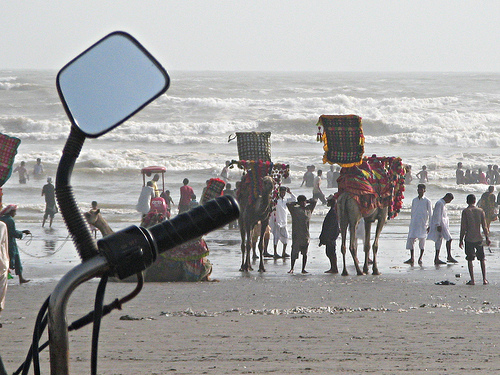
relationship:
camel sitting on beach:
[226, 167, 283, 274] [0, 225, 498, 374]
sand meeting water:
[212, 251, 239, 349] [211, 79, 415, 151]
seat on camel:
[316, 112, 368, 169] [338, 156, 403, 280]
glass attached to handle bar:
[58, 34, 168, 140] [19, 66, 244, 293]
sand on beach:
[1, 259, 499, 372] [2, 160, 499, 373]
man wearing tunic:
[388, 160, 445, 296] [406, 199, 429, 249]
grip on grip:
[98, 193, 240, 280] [98, 193, 240, 280]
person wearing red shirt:
[179, 176, 194, 208] [177, 183, 192, 202]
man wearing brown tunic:
[286, 195, 317, 274] [286, 197, 316, 238]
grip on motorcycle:
[98, 193, 240, 280] [1, 30, 244, 372]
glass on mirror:
[58, 34, 167, 132] [55, 24, 170, 260]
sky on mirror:
[90, 55, 142, 107] [56, 30, 170, 137]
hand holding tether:
[19, 230, 29, 237] [13, 224, 82, 257]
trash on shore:
[435, 278, 455, 288] [4, 263, 498, 372]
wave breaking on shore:
[78, 144, 158, 172] [13, 203, 499, 278]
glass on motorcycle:
[58, 34, 168, 140] [1, 30, 244, 372]